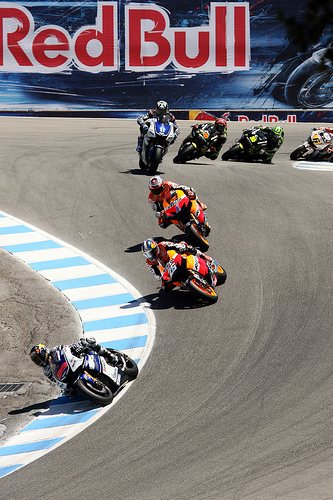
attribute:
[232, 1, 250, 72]
letter — part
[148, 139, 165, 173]
wheel — part, black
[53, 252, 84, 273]
line — part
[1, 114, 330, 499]
road — part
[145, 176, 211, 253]
motorcycle — red, yellow, third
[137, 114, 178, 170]
motorcycle — blue, fourth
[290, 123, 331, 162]
motorcycle — white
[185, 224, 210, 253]
tire — red, black, rubber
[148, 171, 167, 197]
helmet — white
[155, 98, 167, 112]
helmet — black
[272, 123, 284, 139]
helmet — green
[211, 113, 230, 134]
helmet — red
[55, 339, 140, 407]
motorcycle — first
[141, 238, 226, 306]
motorcycle — 2nd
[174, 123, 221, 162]
motorcycle — fifth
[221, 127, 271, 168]
motorcycle — 6th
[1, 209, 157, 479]
stripes — blue